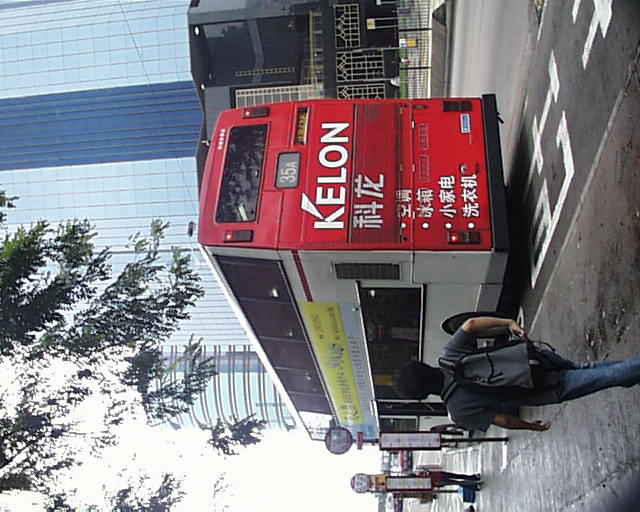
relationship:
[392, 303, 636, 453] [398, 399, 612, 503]
man walking in sidewalk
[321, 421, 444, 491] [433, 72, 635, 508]
sign board in sidewalk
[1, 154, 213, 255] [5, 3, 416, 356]
wall on building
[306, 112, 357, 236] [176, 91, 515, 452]
text on bus